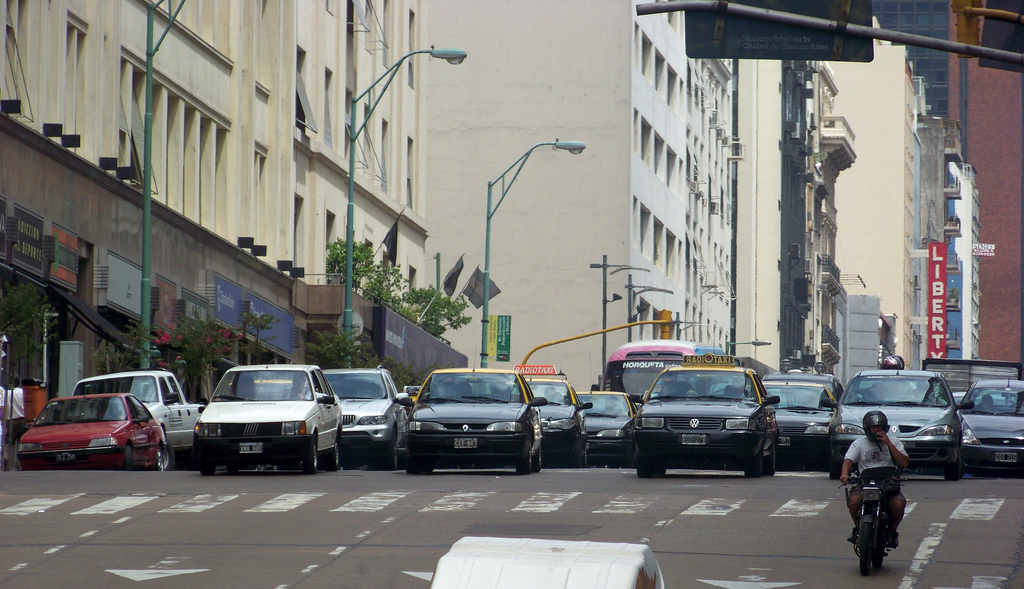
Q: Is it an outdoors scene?
A: Yes, it is outdoors.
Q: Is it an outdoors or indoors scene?
A: It is outdoors.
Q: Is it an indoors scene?
A: No, it is outdoors.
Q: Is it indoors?
A: No, it is outdoors.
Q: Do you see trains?
A: No, there are no trains.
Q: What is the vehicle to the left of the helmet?
A: The vehicle is a car.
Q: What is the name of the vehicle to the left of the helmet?
A: The vehicle is a car.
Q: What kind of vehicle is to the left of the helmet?
A: The vehicle is a car.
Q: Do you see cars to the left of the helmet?
A: Yes, there is a car to the left of the helmet.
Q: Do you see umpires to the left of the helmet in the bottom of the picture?
A: No, there is a car to the left of the helmet.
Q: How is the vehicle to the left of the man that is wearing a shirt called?
A: The vehicle is a car.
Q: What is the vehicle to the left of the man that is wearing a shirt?
A: The vehicle is a car.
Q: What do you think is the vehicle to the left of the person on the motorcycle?
A: The vehicle is a car.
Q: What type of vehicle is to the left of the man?
A: The vehicle is a car.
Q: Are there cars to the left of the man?
A: Yes, there is a car to the left of the man.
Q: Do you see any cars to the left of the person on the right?
A: Yes, there is a car to the left of the man.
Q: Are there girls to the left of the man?
A: No, there is a car to the left of the man.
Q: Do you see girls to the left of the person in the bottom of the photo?
A: No, there is a car to the left of the man.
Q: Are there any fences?
A: No, there are no fences.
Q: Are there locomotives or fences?
A: No, there are no fences or locomotives.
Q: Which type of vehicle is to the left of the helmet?
A: The vehicle is a car.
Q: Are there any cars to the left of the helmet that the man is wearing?
A: Yes, there is a car to the left of the helmet.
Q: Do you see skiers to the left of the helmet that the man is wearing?
A: No, there is a car to the left of the helmet.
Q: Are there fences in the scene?
A: No, there are no fences.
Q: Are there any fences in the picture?
A: No, there are no fences.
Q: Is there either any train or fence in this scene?
A: No, there are no fences or trains.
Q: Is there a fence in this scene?
A: No, there are no fences.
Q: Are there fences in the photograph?
A: No, there are no fences.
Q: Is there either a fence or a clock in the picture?
A: No, there are no fences or clocks.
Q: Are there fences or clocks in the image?
A: No, there are no fences or clocks.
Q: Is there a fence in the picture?
A: No, there are no fences.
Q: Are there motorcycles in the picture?
A: Yes, there is a motorcycle.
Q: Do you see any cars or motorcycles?
A: Yes, there is a motorcycle.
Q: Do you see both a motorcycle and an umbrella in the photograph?
A: No, there is a motorcycle but no umbrellas.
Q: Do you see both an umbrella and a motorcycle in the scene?
A: No, there is a motorcycle but no umbrellas.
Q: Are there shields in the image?
A: No, there are no shields.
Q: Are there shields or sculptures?
A: No, there are no shields or sculptures.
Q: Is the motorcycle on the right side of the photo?
A: Yes, the motorcycle is on the right of the image.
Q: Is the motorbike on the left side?
A: No, the motorbike is on the right of the image.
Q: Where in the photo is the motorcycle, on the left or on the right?
A: The motorcycle is on the right of the image.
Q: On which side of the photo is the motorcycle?
A: The motorcycle is on the right of the image.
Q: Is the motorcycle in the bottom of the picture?
A: Yes, the motorcycle is in the bottom of the image.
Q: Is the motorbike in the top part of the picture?
A: No, the motorbike is in the bottom of the image.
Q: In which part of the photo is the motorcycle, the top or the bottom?
A: The motorcycle is in the bottom of the image.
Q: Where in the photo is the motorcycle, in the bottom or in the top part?
A: The motorcycle is in the bottom of the image.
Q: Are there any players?
A: No, there are no players.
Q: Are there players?
A: No, there are no players.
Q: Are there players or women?
A: No, there are no players or women.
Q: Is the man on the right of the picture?
A: Yes, the man is on the right of the image.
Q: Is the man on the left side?
A: No, the man is on the right of the image.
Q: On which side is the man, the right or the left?
A: The man is on the right of the image.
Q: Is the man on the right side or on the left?
A: The man is on the right of the image.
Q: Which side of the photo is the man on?
A: The man is on the right of the image.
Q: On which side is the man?
A: The man is on the right of the image.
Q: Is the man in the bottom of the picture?
A: Yes, the man is in the bottom of the image.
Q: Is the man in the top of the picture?
A: No, the man is in the bottom of the image.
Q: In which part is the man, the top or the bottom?
A: The man is in the bottom of the image.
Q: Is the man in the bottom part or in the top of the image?
A: The man is in the bottom of the image.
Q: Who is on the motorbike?
A: The man is on the motorbike.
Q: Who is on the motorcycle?
A: The man is on the motorbike.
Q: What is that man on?
A: The man is on the motorbike.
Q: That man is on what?
A: The man is on the motorbike.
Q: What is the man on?
A: The man is on the motorbike.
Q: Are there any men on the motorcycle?
A: Yes, there is a man on the motorcycle.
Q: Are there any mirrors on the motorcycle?
A: No, there is a man on the motorcycle.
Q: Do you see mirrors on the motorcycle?
A: No, there is a man on the motorcycle.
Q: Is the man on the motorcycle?
A: Yes, the man is on the motorcycle.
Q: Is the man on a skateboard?
A: No, the man is on the motorcycle.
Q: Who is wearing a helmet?
A: The man is wearing a helmet.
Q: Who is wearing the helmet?
A: The man is wearing a helmet.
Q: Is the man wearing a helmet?
A: Yes, the man is wearing a helmet.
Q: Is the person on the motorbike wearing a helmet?
A: Yes, the man is wearing a helmet.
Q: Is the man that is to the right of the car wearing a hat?
A: No, the man is wearing a helmet.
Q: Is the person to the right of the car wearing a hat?
A: No, the man is wearing a helmet.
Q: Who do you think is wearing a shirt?
A: The man is wearing a shirt.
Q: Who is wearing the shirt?
A: The man is wearing a shirt.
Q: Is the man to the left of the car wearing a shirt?
A: Yes, the man is wearing a shirt.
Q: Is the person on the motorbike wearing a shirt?
A: Yes, the man is wearing a shirt.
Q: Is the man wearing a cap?
A: No, the man is wearing a shirt.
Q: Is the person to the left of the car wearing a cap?
A: No, the man is wearing a shirt.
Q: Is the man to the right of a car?
A: No, the man is to the left of a car.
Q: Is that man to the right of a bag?
A: No, the man is to the right of a car.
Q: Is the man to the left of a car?
A: No, the man is to the right of a car.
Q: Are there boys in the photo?
A: No, there are no boys.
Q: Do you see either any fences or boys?
A: No, there are no boys or fences.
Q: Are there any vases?
A: No, there are no vases.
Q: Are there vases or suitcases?
A: No, there are no vases or suitcases.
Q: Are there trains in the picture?
A: No, there are no trains.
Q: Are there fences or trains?
A: No, there are no trains or fences.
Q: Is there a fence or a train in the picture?
A: No, there are no trains or fences.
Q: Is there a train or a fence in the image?
A: No, there are no trains or fences.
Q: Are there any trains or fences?
A: No, there are no trains or fences.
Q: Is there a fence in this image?
A: No, there are no fences.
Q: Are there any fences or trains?
A: No, there are no fences or trains.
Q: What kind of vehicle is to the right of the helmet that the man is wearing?
A: The vehicle is a car.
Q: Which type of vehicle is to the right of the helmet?
A: The vehicle is a car.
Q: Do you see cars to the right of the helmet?
A: Yes, there is a car to the right of the helmet.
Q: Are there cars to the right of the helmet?
A: Yes, there is a car to the right of the helmet.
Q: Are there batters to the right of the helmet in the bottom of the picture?
A: No, there is a car to the right of the helmet.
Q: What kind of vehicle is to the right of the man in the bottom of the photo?
A: The vehicle is a car.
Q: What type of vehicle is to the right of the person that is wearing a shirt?
A: The vehicle is a car.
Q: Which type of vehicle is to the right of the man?
A: The vehicle is a car.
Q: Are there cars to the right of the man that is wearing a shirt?
A: Yes, there is a car to the right of the man.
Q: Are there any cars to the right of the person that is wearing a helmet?
A: Yes, there is a car to the right of the man.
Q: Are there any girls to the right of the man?
A: No, there is a car to the right of the man.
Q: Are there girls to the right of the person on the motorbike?
A: No, there is a car to the right of the man.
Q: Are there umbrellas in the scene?
A: No, there are no umbrellas.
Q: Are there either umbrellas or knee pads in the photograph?
A: No, there are no umbrellas or knee pads.